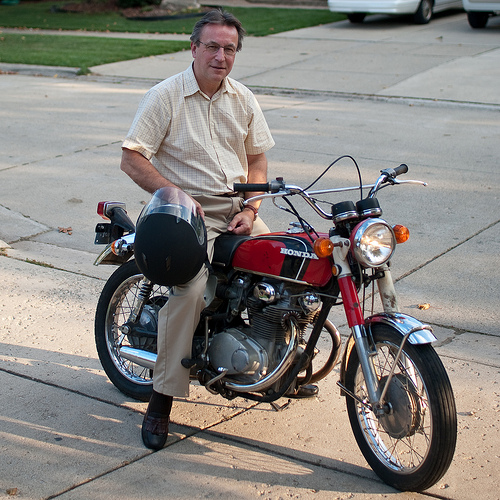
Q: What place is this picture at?
A: It is at the street.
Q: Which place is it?
A: It is a street.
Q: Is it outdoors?
A: Yes, it is outdoors.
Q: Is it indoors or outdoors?
A: It is outdoors.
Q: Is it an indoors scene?
A: No, it is outdoors.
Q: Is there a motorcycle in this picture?
A: Yes, there is a motorcycle.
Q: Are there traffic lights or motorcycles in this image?
A: Yes, there is a motorcycle.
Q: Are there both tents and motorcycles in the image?
A: No, there is a motorcycle but no tents.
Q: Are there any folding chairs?
A: No, there are no folding chairs.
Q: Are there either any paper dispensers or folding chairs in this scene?
A: No, there are no folding chairs or paper dispensers.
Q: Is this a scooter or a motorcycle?
A: This is a motorcycle.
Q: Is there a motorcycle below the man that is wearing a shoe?
A: Yes, there is a motorcycle below the man.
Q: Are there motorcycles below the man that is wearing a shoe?
A: Yes, there is a motorcycle below the man.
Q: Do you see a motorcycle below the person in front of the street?
A: Yes, there is a motorcycle below the man.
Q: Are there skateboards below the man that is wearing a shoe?
A: No, there is a motorcycle below the man.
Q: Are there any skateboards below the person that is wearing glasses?
A: No, there is a motorcycle below the man.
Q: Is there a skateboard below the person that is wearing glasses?
A: No, there is a motorcycle below the man.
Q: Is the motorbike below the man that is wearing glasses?
A: Yes, the motorbike is below the man.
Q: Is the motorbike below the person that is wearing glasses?
A: Yes, the motorbike is below the man.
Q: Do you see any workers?
A: No, there are no workers.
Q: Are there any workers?
A: No, there are no workers.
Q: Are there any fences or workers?
A: No, there are no workers or fences.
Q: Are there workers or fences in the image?
A: No, there are no workers or fences.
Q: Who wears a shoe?
A: The man wears a shoe.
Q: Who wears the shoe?
A: The man wears a shoe.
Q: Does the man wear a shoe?
A: Yes, the man wears a shoe.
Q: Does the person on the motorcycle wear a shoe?
A: Yes, the man wears a shoe.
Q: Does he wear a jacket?
A: No, the man wears a shoe.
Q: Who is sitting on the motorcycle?
A: The man is sitting on the motorbike.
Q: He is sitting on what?
A: The man is sitting on the motorbike.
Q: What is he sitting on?
A: The man is sitting on the motorbike.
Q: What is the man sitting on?
A: The man is sitting on the motorbike.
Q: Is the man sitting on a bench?
A: No, the man is sitting on the motorbike.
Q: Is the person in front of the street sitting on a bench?
A: No, the man is sitting on the motorbike.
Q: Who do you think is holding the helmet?
A: The man is holding the helmet.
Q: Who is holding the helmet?
A: The man is holding the helmet.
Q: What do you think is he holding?
A: The man is holding the helmet.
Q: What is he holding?
A: The man is holding the helmet.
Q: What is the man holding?
A: The man is holding the helmet.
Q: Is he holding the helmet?
A: Yes, the man is holding the helmet.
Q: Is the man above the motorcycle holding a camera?
A: No, the man is holding the helmet.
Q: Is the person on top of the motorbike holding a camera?
A: No, the man is holding the helmet.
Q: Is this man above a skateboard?
A: No, the man is above the motorbike.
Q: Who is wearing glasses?
A: The man is wearing glasses.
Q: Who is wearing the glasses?
A: The man is wearing glasses.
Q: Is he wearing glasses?
A: Yes, the man is wearing glasses.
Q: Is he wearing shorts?
A: No, the man is wearing glasses.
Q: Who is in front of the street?
A: The man is in front of the street.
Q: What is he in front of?
A: The man is in front of the street.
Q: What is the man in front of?
A: The man is in front of the street.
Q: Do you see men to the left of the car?
A: Yes, there is a man to the left of the car.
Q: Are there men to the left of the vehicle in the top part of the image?
A: Yes, there is a man to the left of the car.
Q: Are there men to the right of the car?
A: No, the man is to the left of the car.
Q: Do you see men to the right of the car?
A: No, the man is to the left of the car.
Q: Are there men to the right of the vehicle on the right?
A: No, the man is to the left of the car.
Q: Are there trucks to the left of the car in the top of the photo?
A: No, there is a man to the left of the car.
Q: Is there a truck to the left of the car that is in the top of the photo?
A: No, there is a man to the left of the car.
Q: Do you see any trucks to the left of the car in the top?
A: No, there is a man to the left of the car.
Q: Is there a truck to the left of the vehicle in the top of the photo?
A: No, there is a man to the left of the car.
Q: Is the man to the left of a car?
A: Yes, the man is to the left of a car.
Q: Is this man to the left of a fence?
A: No, the man is to the left of a car.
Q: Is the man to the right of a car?
A: No, the man is to the left of a car.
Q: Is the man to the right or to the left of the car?
A: The man is to the left of the car.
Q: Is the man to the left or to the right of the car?
A: The man is to the left of the car.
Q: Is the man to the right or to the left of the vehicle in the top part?
A: The man is to the left of the car.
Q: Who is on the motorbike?
A: The man is on the motorbike.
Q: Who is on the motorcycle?
A: The man is on the motorbike.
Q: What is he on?
A: The man is on the motorcycle.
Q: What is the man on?
A: The man is on the motorcycle.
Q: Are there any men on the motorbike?
A: Yes, there is a man on the motorbike.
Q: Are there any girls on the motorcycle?
A: No, there is a man on the motorcycle.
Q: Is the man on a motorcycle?
A: Yes, the man is on a motorcycle.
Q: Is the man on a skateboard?
A: No, the man is on a motorcycle.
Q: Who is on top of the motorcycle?
A: The man is on top of the motorbike.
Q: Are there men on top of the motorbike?
A: Yes, there is a man on top of the motorbike.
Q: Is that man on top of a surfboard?
A: No, the man is on top of the motorcycle.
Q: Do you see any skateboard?
A: No, there are no skateboards.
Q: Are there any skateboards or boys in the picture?
A: No, there are no skateboards or boys.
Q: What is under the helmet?
A: The shoe is under the helmet.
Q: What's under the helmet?
A: The shoe is under the helmet.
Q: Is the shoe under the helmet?
A: Yes, the shoe is under the helmet.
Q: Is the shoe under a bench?
A: No, the shoe is under the helmet.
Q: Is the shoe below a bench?
A: No, the shoe is below the helmet.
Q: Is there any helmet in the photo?
A: Yes, there is a helmet.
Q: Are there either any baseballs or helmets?
A: Yes, there is a helmet.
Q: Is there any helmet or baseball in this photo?
A: Yes, there is a helmet.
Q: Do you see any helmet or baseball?
A: Yes, there is a helmet.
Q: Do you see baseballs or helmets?
A: Yes, there is a helmet.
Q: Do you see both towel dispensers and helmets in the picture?
A: No, there is a helmet but no towel dispensers.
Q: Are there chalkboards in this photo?
A: No, there are no chalkboards.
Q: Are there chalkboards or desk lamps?
A: No, there are no chalkboards or desk lamps.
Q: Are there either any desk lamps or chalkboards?
A: No, there are no chalkboards or desk lamps.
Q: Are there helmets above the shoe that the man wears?
A: Yes, there is a helmet above the shoe.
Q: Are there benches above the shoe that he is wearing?
A: No, there is a helmet above the shoe.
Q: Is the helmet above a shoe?
A: Yes, the helmet is above a shoe.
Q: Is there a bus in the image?
A: No, there are no buses.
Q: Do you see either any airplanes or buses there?
A: No, there are no buses or airplanes.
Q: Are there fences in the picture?
A: No, there are no fences.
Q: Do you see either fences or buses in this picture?
A: No, there are no fences or buses.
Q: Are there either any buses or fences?
A: No, there are no fences or buses.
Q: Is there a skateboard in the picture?
A: No, there are no skateboards.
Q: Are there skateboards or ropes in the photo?
A: No, there are no skateboards or ropes.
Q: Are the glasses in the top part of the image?
A: Yes, the glasses are in the top of the image.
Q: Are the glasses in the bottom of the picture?
A: No, the glasses are in the top of the image.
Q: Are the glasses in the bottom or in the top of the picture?
A: The glasses are in the top of the image.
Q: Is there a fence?
A: No, there are no fences.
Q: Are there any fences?
A: No, there are no fences.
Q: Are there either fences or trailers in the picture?
A: No, there are no fences or trailers.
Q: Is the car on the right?
A: Yes, the car is on the right of the image.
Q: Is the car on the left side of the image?
A: No, the car is on the right of the image.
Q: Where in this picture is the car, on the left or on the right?
A: The car is on the right of the image.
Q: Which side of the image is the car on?
A: The car is on the right of the image.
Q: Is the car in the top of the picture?
A: Yes, the car is in the top of the image.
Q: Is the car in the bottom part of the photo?
A: No, the car is in the top of the image.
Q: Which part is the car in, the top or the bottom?
A: The car is in the top of the image.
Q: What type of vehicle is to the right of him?
A: The vehicle is a car.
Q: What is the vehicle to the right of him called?
A: The vehicle is a car.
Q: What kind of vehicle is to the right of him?
A: The vehicle is a car.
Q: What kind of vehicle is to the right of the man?
A: The vehicle is a car.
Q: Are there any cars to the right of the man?
A: Yes, there is a car to the right of the man.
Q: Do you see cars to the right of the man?
A: Yes, there is a car to the right of the man.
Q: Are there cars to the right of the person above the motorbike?
A: Yes, there is a car to the right of the man.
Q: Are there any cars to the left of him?
A: No, the car is to the right of the man.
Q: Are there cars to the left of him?
A: No, the car is to the right of the man.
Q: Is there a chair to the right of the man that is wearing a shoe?
A: No, there is a car to the right of the man.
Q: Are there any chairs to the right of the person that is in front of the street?
A: No, there is a car to the right of the man.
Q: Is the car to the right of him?
A: Yes, the car is to the right of the man.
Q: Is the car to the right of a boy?
A: No, the car is to the right of the man.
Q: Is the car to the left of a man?
A: No, the car is to the right of a man.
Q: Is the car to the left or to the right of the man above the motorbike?
A: The car is to the right of the man.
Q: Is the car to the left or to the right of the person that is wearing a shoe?
A: The car is to the right of the man.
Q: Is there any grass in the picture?
A: Yes, there is grass.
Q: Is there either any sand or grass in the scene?
A: Yes, there is grass.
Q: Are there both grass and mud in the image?
A: No, there is grass but no mud.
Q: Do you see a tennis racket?
A: No, there are no rackets.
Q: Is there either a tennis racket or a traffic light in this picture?
A: No, there are no rackets or traffic lights.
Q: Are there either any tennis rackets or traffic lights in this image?
A: No, there are no tennis rackets or traffic lights.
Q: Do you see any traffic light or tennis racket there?
A: No, there are no rackets or traffic lights.